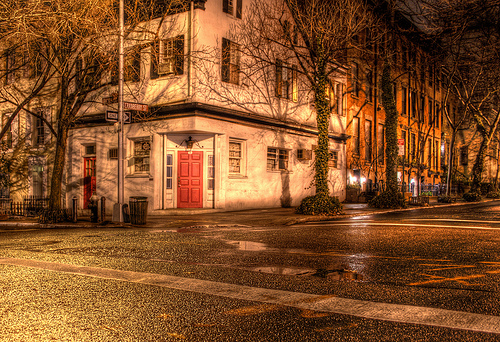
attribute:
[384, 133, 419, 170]
sign — red and white, street sign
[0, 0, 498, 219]
buildings — tall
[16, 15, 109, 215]
tree — tall, leafless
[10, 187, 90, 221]
fence — black, metal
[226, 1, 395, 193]
tree — leafless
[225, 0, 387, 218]
tree — large, tall, leafless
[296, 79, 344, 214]
vines — green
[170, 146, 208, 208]
door — red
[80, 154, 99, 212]
door — red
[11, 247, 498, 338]
line — white, painted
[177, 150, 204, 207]
door — red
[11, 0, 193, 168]
trees — large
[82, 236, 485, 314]
road — grey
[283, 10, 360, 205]
tree — tall, leafless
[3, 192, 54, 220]
fence — Low 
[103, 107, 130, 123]
sign — black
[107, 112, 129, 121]
arrow — white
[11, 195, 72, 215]
fence — black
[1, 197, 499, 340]
road — grey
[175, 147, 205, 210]
doorway — red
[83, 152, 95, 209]
door — red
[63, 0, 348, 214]
building — white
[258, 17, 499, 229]
tree — leafless, tall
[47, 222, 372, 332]
lit road — gray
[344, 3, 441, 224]
leafless tree — tall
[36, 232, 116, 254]
puddles — small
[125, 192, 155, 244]
trash can — black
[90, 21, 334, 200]
building — white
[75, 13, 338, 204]
building — white